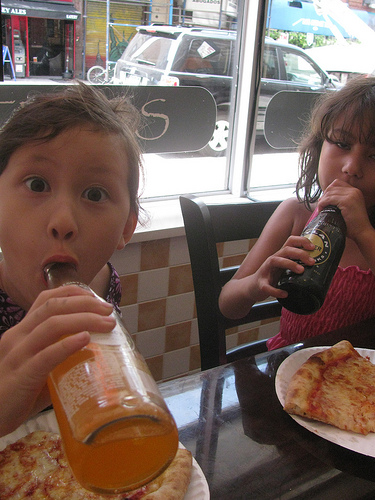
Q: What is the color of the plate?
A: White.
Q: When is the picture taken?
A: Daytime.